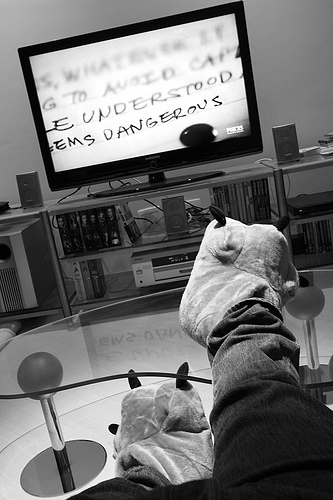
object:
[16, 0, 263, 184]
screen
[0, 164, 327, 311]
shelves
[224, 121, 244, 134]
image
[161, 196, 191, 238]
speaker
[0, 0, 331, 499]
office building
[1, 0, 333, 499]
room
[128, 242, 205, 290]
dvd player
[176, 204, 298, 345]
slipper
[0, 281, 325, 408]
glass top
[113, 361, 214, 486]
animal slipper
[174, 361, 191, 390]
claw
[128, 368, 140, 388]
claw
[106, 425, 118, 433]
claw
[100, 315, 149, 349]
glass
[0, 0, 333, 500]
table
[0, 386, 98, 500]
floor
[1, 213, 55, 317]
speaker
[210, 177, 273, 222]
dvd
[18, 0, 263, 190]
flat screen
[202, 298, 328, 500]
jeans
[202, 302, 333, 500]
leg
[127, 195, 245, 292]
devices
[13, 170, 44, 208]
speaker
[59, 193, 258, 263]
shelf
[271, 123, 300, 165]
speaker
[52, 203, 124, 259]
tapes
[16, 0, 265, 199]
t.v.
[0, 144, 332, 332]
t.v. stand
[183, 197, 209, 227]
cables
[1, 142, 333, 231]
tabletop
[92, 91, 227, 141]
word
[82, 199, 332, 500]
person